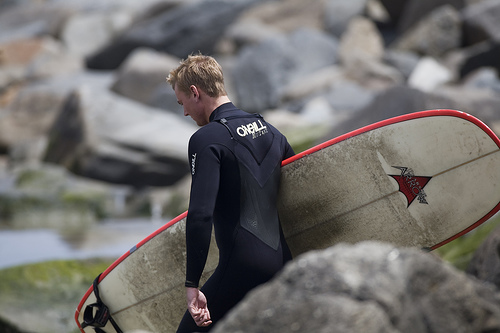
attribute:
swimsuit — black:
[175, 105, 293, 332]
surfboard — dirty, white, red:
[77, 108, 498, 332]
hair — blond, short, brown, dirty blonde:
[166, 53, 230, 96]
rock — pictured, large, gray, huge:
[43, 87, 199, 185]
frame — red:
[74, 108, 499, 331]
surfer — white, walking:
[166, 53, 294, 332]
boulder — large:
[208, 241, 500, 331]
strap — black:
[83, 273, 121, 332]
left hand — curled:
[187, 289, 211, 324]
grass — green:
[3, 213, 499, 285]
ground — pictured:
[4, 160, 499, 332]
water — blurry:
[0, 219, 172, 270]